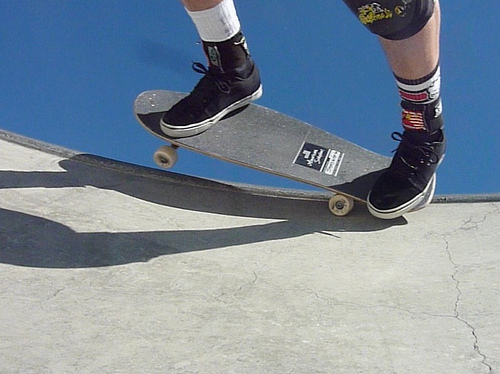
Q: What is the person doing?
A: Skateboarding.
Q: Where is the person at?
A: Skate park.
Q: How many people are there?
A: One.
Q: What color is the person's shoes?
A: Black.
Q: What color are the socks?
A: White.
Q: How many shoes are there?
A: Two.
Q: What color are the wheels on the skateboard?
A: Yellow.